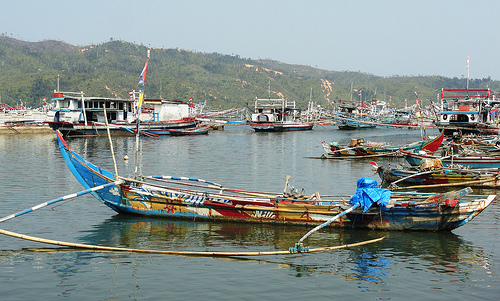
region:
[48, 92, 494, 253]
colorful boats on the water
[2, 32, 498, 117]
green hills in the background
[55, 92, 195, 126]
a white building in the background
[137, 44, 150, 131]
a colorful flag on the boat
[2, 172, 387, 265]
an outrigger on the small boat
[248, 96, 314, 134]
a large black and white boat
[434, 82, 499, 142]
a large colorful boat in the background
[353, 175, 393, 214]
a bright blue material covering something on the boat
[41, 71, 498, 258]
a boat harbor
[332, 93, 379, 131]
a large turquoise colored boat in background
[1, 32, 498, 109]
Green mountains in bakground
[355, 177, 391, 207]
Blue tarp on boat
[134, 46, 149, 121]
Two flags on the boat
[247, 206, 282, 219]
Nille written on the boat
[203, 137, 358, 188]
Water surrounding the boat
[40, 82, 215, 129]
Large white boat in the background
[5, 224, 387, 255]
Long bamboo stick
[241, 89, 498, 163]
Many boats behind boat in foreground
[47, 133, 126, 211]
Blue tip of boat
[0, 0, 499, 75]
Hazy sky in background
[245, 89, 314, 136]
White boat going down the river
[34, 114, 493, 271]
Small canoe in the river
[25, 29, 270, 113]
Mountains in the distance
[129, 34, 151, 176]
Flag on a small canoe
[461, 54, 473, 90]
Flag pole on top of a boat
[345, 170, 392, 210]
Blue tarp on a canoe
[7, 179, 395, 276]
Balancing rails on a canoe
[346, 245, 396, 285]
Reflection of the tarp in the water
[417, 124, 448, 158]
Red flag on a boat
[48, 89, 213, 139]
House boat in the water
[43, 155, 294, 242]
the boat has blue stripes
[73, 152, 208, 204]
the boat has blue stripes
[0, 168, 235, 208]
the boat has blue stripes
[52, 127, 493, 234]
A colorfully painted boat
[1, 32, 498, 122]
Mountains in the background, covered with vegetation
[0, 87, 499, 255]
Many small colorful boats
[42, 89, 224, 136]
A large white boat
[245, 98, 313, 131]
A large white boat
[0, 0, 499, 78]
A hazy blue sky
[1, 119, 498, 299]
A large body of water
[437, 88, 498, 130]
A large white boat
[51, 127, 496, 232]
A small boat, hand-painted boat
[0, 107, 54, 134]
A dock at the edge of the water